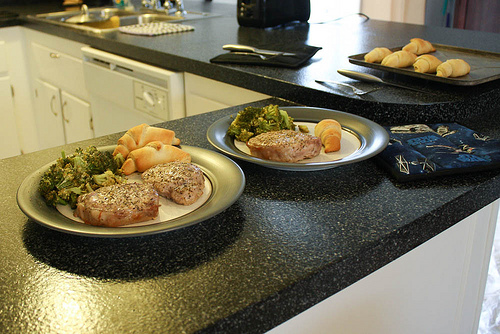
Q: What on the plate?
A: Food.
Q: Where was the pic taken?
A: In the kitchen.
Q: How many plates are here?
A: 2.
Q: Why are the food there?
A: They will be eaten.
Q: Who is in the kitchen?
A: No one.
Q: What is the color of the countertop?
A: Black.